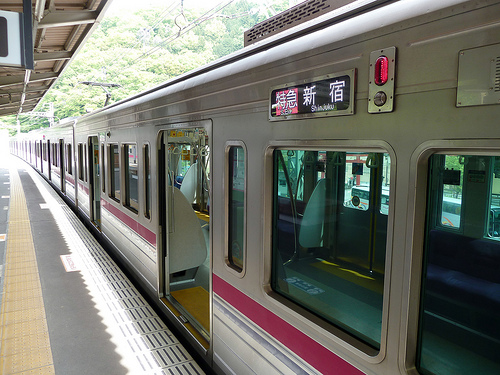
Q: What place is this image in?
A: It is at the station.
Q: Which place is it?
A: It is a station.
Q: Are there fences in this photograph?
A: No, there are no fences.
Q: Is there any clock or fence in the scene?
A: No, there are no fences or clocks.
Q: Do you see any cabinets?
A: No, there are no cabinets.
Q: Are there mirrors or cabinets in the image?
A: No, there are no cabinets or mirrors.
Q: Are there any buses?
A: No, there are no buses.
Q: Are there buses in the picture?
A: No, there are no buses.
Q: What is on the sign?
A: The characters are on the sign.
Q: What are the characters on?
A: The characters are on the sign.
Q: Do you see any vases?
A: No, there are no vases.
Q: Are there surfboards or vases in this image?
A: No, there are no vases or surfboards.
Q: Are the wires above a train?
A: Yes, the wires are above a train.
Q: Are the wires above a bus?
A: No, the wires are above a train.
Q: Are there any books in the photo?
A: No, there are no books.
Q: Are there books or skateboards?
A: No, there are no books or skateboards.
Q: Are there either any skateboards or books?
A: No, there are no books or skateboards.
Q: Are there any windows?
A: Yes, there are windows.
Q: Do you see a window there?
A: Yes, there are windows.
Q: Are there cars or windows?
A: Yes, there are windows.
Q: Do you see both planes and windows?
A: No, there are windows but no airplanes.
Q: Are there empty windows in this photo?
A: Yes, there are empty windows.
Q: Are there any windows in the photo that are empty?
A: Yes, there are windows that are empty.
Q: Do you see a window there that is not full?
A: Yes, there are empty windows.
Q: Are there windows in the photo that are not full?
A: Yes, there are empty windows.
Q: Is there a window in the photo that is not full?
A: Yes, there are empty windows.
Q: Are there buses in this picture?
A: No, there are no buses.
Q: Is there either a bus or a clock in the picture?
A: No, there are no buses or clocks.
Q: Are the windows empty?
A: Yes, the windows are empty.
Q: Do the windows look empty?
A: Yes, the windows are empty.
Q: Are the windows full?
A: No, the windows are empty.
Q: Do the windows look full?
A: No, the windows are empty.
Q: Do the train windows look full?
A: No, the windows are empty.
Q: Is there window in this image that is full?
A: No, there are windows but they are empty.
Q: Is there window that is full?
A: No, there are windows but they are empty.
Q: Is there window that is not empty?
A: No, there are windows but they are empty.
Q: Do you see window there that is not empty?
A: No, there are windows but they are empty.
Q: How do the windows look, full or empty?
A: The windows are empty.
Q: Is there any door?
A: Yes, there is a door.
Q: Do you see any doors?
A: Yes, there is a door.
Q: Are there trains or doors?
A: Yes, there is a door.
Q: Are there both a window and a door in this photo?
A: Yes, there are both a door and a window.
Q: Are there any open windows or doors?
A: Yes, there is an open door.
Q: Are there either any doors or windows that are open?
A: Yes, the door is open.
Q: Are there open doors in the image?
A: Yes, there is an open door.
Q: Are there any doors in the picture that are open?
A: Yes, there is a door that is open.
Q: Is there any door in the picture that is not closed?
A: Yes, there is a open door.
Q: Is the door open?
A: Yes, the door is open.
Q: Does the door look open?
A: Yes, the door is open.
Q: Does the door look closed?
A: No, the door is open.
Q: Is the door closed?
A: No, the door is open.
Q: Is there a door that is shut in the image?
A: No, there is a door but it is open.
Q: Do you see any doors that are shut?
A: No, there is a door but it is open.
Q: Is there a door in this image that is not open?
A: No, there is a door but it is open.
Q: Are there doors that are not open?
A: No, there is a door but it is open.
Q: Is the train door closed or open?
A: The door is open.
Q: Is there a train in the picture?
A: Yes, there is a train.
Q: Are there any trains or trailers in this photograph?
A: Yes, there is a train.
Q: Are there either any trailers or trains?
A: Yes, there is a train.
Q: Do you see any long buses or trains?
A: Yes, there is a long train.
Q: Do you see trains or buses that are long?
A: Yes, the train is long.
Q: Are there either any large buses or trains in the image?
A: Yes, there is a large train.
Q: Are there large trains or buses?
A: Yes, there is a large train.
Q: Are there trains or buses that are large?
A: Yes, the train is large.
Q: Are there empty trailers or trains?
A: Yes, there is an empty train.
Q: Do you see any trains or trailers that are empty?
A: Yes, the train is empty.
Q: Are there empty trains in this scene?
A: Yes, there is an empty train.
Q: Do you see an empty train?
A: Yes, there is an empty train.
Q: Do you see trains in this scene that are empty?
A: Yes, there is a train that is empty.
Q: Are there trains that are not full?
A: Yes, there is a empty train.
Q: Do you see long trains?
A: Yes, there is a long train.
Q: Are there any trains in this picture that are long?
A: Yes, there is a train that is long.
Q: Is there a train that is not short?
A: Yes, there is a long train.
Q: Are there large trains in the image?
A: Yes, there is a large train.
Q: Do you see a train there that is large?
A: Yes, there is a train that is large.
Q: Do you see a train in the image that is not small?
A: Yes, there is a large train.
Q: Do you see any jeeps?
A: No, there are no jeeps.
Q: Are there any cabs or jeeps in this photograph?
A: No, there are no jeeps or cabs.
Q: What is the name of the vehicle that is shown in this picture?
A: The vehicle is a train.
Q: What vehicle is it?
A: The vehicle is a train.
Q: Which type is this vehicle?
A: This is a train.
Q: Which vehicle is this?
A: This is a train.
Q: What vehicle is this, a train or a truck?
A: This is a train.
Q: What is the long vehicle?
A: The vehicle is a train.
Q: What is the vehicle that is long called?
A: The vehicle is a train.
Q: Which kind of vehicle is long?
A: The vehicle is a train.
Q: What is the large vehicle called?
A: The vehicle is a train.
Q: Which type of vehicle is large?
A: The vehicle is a train.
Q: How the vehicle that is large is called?
A: The vehicle is a train.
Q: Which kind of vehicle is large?
A: The vehicle is a train.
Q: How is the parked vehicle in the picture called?
A: The vehicle is a train.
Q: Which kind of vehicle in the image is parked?
A: The vehicle is a train.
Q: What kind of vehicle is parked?
A: The vehicle is a train.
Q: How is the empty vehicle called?
A: The vehicle is a train.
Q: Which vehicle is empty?
A: The vehicle is a train.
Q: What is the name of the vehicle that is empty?
A: The vehicle is a train.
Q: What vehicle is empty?
A: The vehicle is a train.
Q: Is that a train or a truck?
A: That is a train.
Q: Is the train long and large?
A: Yes, the train is long and large.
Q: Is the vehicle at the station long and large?
A: Yes, the train is long and large.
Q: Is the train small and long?
A: No, the train is long but large.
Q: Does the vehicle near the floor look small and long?
A: No, the train is long but large.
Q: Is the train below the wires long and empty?
A: Yes, the train is long and empty.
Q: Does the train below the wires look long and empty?
A: Yes, the train is long and empty.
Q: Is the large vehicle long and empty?
A: Yes, the train is long and empty.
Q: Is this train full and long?
A: No, the train is long but empty.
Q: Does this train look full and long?
A: No, the train is long but empty.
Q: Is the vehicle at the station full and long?
A: No, the train is long but empty.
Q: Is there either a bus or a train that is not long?
A: No, there is a train but it is long.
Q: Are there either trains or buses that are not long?
A: No, there is a train but it is long.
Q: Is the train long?
A: Yes, the train is long.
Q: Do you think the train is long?
A: Yes, the train is long.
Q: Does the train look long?
A: Yes, the train is long.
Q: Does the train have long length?
A: Yes, the train is long.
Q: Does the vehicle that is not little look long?
A: Yes, the train is long.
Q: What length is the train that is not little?
A: The train is long.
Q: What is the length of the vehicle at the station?
A: The train is long.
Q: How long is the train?
A: The train is long.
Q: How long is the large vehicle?
A: The train is long.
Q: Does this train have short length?
A: No, the train is long.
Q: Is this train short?
A: No, the train is long.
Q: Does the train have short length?
A: No, the train is long.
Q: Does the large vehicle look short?
A: No, the train is long.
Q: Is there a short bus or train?
A: No, there is a train but it is long.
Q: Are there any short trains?
A: No, there is a train but it is long.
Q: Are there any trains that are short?
A: No, there is a train but it is long.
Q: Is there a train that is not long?
A: No, there is a train but it is long.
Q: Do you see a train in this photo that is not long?
A: No, there is a train but it is long.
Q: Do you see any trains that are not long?
A: No, there is a train but it is long.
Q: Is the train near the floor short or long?
A: The train is long.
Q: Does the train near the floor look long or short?
A: The train is long.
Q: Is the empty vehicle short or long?
A: The train is long.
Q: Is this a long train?
A: Yes, this is a long train.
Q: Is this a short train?
A: No, this is a long train.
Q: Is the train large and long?
A: Yes, the train is large and long.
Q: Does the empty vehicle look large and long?
A: Yes, the train is large and long.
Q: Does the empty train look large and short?
A: No, the train is large but long.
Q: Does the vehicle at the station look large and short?
A: No, the train is large but long.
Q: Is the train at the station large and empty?
A: Yes, the train is large and empty.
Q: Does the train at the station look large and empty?
A: Yes, the train is large and empty.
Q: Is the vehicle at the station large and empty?
A: Yes, the train is large and empty.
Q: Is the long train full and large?
A: No, the train is large but empty.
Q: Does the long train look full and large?
A: No, the train is large but empty.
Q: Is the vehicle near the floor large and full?
A: No, the train is large but empty.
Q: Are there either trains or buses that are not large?
A: No, there is a train but it is large.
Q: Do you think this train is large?
A: Yes, the train is large.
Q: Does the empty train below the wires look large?
A: Yes, the train is large.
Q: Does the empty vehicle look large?
A: Yes, the train is large.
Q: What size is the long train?
A: The train is large.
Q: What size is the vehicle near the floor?
A: The train is large.